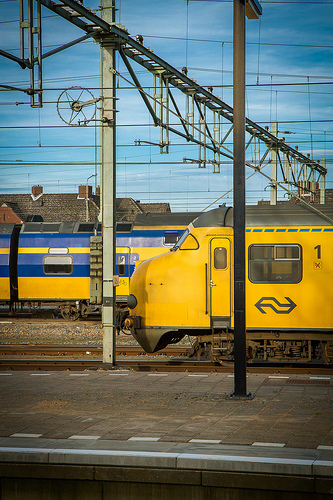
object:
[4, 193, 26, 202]
roof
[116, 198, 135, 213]
roof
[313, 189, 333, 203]
roof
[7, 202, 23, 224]
roof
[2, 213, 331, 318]
train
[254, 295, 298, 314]
diagram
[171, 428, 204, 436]
floor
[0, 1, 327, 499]
picture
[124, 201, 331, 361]
yellow train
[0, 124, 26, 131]
wires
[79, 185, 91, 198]
chimney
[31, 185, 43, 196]
chimney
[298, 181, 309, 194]
chimney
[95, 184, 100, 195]
chimney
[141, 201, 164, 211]
roof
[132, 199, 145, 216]
roof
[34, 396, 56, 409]
dirt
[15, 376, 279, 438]
sidewalk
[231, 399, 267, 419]
bricks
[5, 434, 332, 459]
platform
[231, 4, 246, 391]
pole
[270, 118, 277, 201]
pole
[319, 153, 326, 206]
pole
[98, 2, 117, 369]
pole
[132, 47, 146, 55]
metalic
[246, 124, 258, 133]
metalic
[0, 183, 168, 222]
house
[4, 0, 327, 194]
sky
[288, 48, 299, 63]
clouds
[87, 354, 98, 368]
tracks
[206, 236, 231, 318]
door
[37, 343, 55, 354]
track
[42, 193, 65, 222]
roof